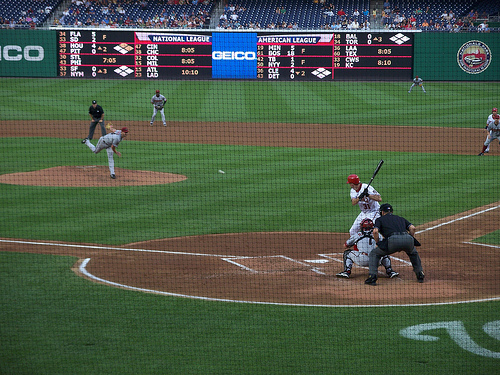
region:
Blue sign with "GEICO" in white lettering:
[210, 30, 262, 79]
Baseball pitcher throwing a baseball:
[77, 122, 132, 179]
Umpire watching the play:
[366, 201, 423, 286]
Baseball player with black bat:
[344, 158, 390, 219]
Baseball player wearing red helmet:
[341, 172, 370, 191]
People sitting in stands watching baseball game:
[3, 4, 498, 26]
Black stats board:
[55, 28, 416, 79]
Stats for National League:
[133, 30, 210, 80]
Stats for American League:
[253, 30, 335, 79]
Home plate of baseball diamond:
[304, 253, 329, 270]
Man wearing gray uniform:
[140, 86, 172, 130]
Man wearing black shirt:
[79, 99, 108, 141]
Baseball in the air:
[214, 164, 231, 184]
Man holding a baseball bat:
[341, 156, 391, 246]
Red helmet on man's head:
[340, 172, 362, 187]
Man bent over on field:
[364, 202, 429, 294]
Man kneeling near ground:
[337, 214, 399, 283]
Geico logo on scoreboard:
[209, 31, 263, 83]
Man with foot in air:
[76, 124, 133, 189]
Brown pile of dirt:
[0, 157, 191, 197]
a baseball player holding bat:
[347, 159, 386, 242]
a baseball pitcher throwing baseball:
[79, 125, 129, 177]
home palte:
[307, 253, 328, 264]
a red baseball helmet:
[346, 173, 361, 184]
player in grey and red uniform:
[80, 124, 130, 181]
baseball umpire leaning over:
[364, 202, 429, 284]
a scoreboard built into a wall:
[54, 28, 415, 80]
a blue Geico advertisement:
[211, 32, 260, 77]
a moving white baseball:
[218, 168, 225, 176]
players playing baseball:
[78, 76, 499, 287]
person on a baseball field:
[72, 116, 140, 181]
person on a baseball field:
[345, 156, 397, 238]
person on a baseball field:
[333, 217, 408, 283]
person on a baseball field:
[357, 198, 432, 295]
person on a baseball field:
[82, 95, 107, 141]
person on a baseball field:
[145, 87, 170, 129]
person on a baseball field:
[404, 74, 429, 95]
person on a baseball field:
[483, 104, 498, 133]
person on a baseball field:
[480, 114, 499, 158]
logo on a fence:
[451, 38, 495, 80]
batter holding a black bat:
[341, 148, 394, 225]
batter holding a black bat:
[306, 129, 405, 269]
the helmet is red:
[319, 166, 364, 203]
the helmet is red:
[339, 167, 384, 203]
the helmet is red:
[338, 161, 370, 195]